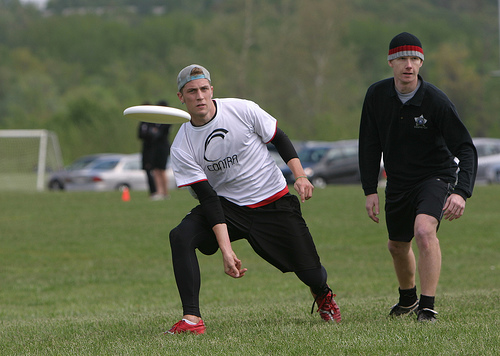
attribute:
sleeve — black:
[193, 169, 242, 240]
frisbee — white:
[113, 93, 209, 136]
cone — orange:
[118, 183, 135, 207]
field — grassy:
[9, 178, 497, 351]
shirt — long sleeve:
[357, 78, 477, 201]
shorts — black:
[379, 174, 455, 239]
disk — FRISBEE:
[117, 94, 197, 129]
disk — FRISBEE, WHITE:
[120, 98, 196, 128]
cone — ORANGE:
[119, 180, 131, 203]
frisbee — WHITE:
[119, 101, 192, 124]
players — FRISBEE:
[157, 28, 479, 335]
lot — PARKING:
[61, 130, 481, 190]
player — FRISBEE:
[161, 58, 344, 336]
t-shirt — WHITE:
[167, 90, 287, 206]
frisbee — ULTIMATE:
[119, 99, 193, 125]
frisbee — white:
[129, 103, 187, 125]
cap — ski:
[388, 37, 429, 60]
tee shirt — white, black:
[167, 101, 283, 208]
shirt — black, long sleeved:
[363, 83, 483, 214]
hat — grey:
[173, 60, 213, 91]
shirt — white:
[166, 98, 296, 208]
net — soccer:
[3, 124, 60, 195]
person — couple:
[162, 63, 338, 321]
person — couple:
[351, 30, 473, 316]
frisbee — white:
[116, 103, 196, 130]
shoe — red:
[152, 314, 211, 339]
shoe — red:
[311, 290, 346, 323]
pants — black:
[378, 169, 455, 246]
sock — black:
[396, 288, 418, 309]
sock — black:
[416, 292, 438, 312]